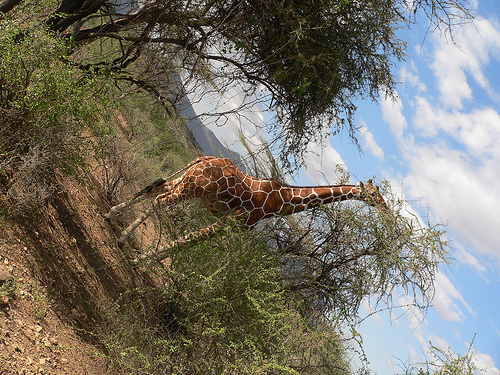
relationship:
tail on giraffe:
[125, 170, 175, 193] [187, 115, 456, 288]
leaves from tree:
[355, 249, 389, 278] [277, 196, 444, 306]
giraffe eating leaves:
[103, 155, 392, 272] [355, 249, 389, 278]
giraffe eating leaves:
[103, 155, 392, 272] [375, 242, 425, 288]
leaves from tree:
[375, 242, 425, 288] [295, 215, 431, 291]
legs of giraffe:
[115, 177, 221, 276] [103, 161, 397, 272]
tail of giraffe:
[112, 156, 210, 204] [114, 152, 394, 247]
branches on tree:
[310, 213, 342, 297] [273, 213, 461, 294]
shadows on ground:
[15, 199, 120, 338] [11, 134, 162, 367]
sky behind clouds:
[378, 17, 490, 337] [409, 11, 498, 315]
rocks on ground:
[8, 270, 63, 370] [8, 172, 136, 371]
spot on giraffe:
[262, 190, 283, 214] [103, 161, 397, 272]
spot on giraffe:
[213, 189, 236, 201] [103, 161, 397, 272]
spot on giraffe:
[280, 180, 296, 204] [103, 161, 397, 272]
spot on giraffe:
[212, 175, 231, 195] [103, 161, 397, 272]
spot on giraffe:
[314, 186, 332, 204] [103, 161, 397, 272]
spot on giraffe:
[265, 186, 283, 220] [109, 161, 402, 251]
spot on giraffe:
[250, 191, 268, 209] [109, 161, 402, 251]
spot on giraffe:
[340, 186, 353, 196] [109, 161, 402, 251]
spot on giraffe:
[191, 171, 209, 188] [109, 161, 402, 251]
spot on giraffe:
[278, 182, 296, 202] [109, 161, 402, 251]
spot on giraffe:
[275, 182, 294, 207] [103, 161, 397, 272]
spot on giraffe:
[217, 180, 227, 193] [103, 161, 397, 272]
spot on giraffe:
[176, 175, 192, 193] [103, 161, 397, 272]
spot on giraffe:
[247, 208, 263, 224] [103, 161, 397, 272]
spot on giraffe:
[220, 189, 231, 204] [103, 155, 392, 272]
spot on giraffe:
[303, 180, 332, 199] [109, 160, 405, 293]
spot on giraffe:
[302, 185, 316, 202] [112, 158, 392, 276]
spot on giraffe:
[289, 186, 301, 198] [109, 150, 398, 239]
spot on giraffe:
[278, 182, 296, 202] [103, 155, 392, 272]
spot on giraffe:
[262, 190, 283, 214] [109, 160, 405, 293]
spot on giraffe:
[248, 191, 268, 210] [103, 155, 392, 272]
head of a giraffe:
[353, 173, 385, 212] [103, 155, 392, 272]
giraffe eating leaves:
[103, 155, 392, 272] [354, 206, 407, 277]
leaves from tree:
[354, 206, 407, 277] [282, 195, 438, 327]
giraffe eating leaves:
[103, 155, 392, 272] [330, 213, 403, 263]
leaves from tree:
[330, 213, 403, 263] [239, 178, 460, 329]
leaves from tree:
[325, 233, 377, 275] [271, 185, 439, 336]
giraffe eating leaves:
[103, 155, 392, 272] [325, 233, 377, 275]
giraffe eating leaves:
[111, 148, 404, 281] [335, 208, 391, 270]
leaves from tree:
[335, 208, 391, 270] [218, 206, 448, 317]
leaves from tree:
[334, 230, 391, 293] [260, 180, 457, 342]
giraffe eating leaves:
[103, 155, 392, 272] [334, 230, 391, 293]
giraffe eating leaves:
[103, 155, 392, 272] [300, 213, 382, 272]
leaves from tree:
[300, 213, 382, 272] [242, 210, 432, 336]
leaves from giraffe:
[310, 219, 386, 269] [111, 148, 404, 281]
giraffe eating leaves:
[111, 148, 404, 281] [310, 219, 386, 269]